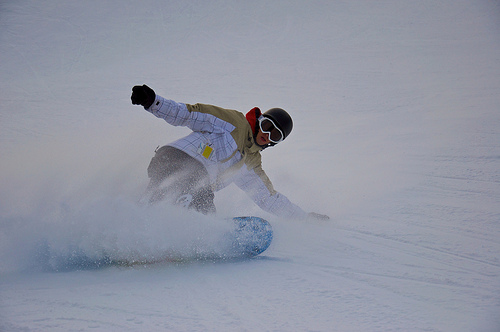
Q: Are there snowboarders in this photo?
A: Yes, there is a snowboarder.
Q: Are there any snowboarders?
A: Yes, there is a snowboarder.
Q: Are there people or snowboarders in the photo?
A: Yes, there is a snowboarder.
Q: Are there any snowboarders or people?
A: Yes, there is a snowboarder.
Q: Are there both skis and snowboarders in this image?
A: No, there is a snowboarder but no skis.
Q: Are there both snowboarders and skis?
A: No, there is a snowboarder but no skis.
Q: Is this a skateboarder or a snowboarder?
A: This is a snowboarder.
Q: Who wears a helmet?
A: The snowboarder wears a helmet.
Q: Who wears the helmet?
A: The snowboarder wears a helmet.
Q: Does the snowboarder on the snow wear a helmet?
A: Yes, the snowboarder wears a helmet.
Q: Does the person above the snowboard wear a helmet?
A: Yes, the snowboarder wears a helmet.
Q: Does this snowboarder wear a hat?
A: No, the snowboarder wears a helmet.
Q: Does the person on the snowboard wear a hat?
A: No, the snowboarder wears a helmet.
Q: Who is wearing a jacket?
A: The snowboarder is wearing a jacket.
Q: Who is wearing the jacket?
A: The snowboarder is wearing a jacket.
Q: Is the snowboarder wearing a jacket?
A: Yes, the snowboarder is wearing a jacket.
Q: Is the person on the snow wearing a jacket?
A: Yes, the snowboarder is wearing a jacket.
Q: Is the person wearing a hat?
A: No, the snowboarder is wearing a jacket.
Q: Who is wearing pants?
A: The snowboarder is wearing pants.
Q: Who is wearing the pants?
A: The snowboarder is wearing pants.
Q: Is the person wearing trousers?
A: Yes, the snowboarder is wearing trousers.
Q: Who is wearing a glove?
A: The snowboarder is wearing a glove.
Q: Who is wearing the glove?
A: The snowboarder is wearing a glove.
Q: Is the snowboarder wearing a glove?
A: Yes, the snowboarder is wearing a glove.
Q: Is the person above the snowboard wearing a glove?
A: Yes, the snowboarder is wearing a glove.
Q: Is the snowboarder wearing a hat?
A: No, the snowboarder is wearing a glove.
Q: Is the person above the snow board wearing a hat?
A: No, the snowboarder is wearing a glove.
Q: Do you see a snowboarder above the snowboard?
A: Yes, there is a snowboarder above the snowboard.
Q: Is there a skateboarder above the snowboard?
A: No, there is a snowboarder above the snowboard.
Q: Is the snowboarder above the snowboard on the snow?
A: Yes, the snowboarder is above the snowboard.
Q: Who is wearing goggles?
A: The snowboarder is wearing goggles.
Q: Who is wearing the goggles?
A: The snowboarder is wearing goggles.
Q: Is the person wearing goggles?
A: Yes, the snowboarder is wearing goggles.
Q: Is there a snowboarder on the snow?
A: Yes, there is a snowboarder on the snow.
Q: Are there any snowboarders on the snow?
A: Yes, there is a snowboarder on the snow.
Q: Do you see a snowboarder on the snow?
A: Yes, there is a snowboarder on the snow.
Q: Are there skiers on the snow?
A: No, there is a snowboarder on the snow.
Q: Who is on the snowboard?
A: The snowboarder is on the snowboard.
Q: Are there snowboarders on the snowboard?
A: Yes, there is a snowboarder on the snowboard.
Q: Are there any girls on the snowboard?
A: No, there is a snowboarder on the snowboard.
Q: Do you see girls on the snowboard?
A: No, there is a snowboarder on the snowboard.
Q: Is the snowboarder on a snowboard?
A: Yes, the snowboarder is on a snowboard.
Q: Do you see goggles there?
A: Yes, there are goggles.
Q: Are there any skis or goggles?
A: Yes, there are goggles.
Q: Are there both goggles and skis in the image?
A: No, there are goggles but no skis.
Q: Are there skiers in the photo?
A: No, there are no skiers.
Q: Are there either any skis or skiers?
A: No, there are no skiers or skis.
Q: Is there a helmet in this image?
A: Yes, there is a helmet.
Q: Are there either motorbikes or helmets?
A: Yes, there is a helmet.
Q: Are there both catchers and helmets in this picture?
A: No, there is a helmet but no catchers.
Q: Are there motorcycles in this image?
A: No, there are no motorcycles.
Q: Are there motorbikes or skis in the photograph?
A: No, there are no motorbikes or skis.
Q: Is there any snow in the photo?
A: Yes, there is snow.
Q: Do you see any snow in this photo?
A: Yes, there is snow.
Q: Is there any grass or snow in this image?
A: Yes, there is snow.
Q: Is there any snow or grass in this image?
A: Yes, there is snow.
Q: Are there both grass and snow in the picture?
A: No, there is snow but no grass.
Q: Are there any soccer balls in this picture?
A: No, there are no soccer balls.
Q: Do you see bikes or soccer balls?
A: No, there are no soccer balls or bikes.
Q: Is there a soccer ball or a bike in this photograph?
A: No, there are no soccer balls or bikes.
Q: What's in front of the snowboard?
A: The snow is in front of the snowboard.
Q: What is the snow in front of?
A: The snow is in front of the snowboard.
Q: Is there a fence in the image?
A: No, there are no fences.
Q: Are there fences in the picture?
A: No, there are no fences.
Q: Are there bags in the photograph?
A: No, there are no bags.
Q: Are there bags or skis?
A: No, there are no bags or skis.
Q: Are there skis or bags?
A: No, there are no bags or skis.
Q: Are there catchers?
A: No, there are no catchers.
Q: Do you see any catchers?
A: No, there are no catchers.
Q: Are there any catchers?
A: No, there are no catchers.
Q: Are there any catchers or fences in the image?
A: No, there are no catchers or fences.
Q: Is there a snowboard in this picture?
A: Yes, there is a snowboard.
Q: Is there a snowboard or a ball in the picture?
A: Yes, there is a snowboard.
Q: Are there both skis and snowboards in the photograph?
A: No, there is a snowboard but no skis.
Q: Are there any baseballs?
A: No, there are no baseballs.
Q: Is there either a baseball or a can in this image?
A: No, there are no baseballs or cans.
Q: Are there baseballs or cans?
A: No, there are no baseballs or cans.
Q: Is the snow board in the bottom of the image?
A: Yes, the snow board is in the bottom of the image.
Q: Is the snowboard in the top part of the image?
A: No, the snowboard is in the bottom of the image.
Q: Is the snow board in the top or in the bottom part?
A: The snow board is in the bottom of the image.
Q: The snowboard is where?
A: The snowboard is on the snow.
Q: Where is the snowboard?
A: The snowboard is on the snow.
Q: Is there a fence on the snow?
A: No, there is a snowboard on the snow.